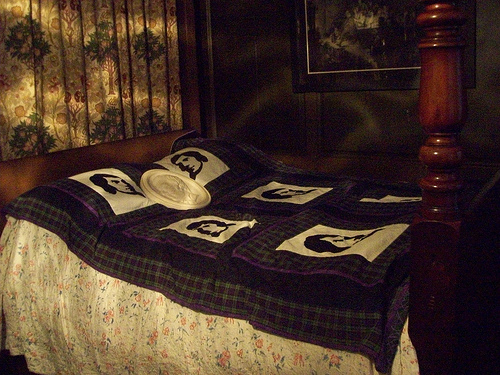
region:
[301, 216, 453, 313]
the pillow has picture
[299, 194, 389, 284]
the pillow has picture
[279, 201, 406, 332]
the pillow has picture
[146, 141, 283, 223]
the pillow has picture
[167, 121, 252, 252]
the pillow has picture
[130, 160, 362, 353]
this is a bed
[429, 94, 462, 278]
the bed is wooden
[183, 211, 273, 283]
this is a blanket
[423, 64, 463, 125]
the bed is brown in color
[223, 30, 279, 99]
this is the wall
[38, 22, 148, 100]
this is a curtain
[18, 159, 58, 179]
the bed is wooden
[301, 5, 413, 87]
this is a picture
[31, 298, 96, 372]
this is a bed cover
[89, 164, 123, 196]
this is a man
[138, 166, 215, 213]
The large white coin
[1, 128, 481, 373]
The dark blanket on the bed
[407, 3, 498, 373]
The post at the end of the bed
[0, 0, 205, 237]
The headboard of the bed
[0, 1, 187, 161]
The curtain behind the headboard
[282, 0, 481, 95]
The painting on the wall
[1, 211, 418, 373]
The light blanket on the bed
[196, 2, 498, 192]
The dark wall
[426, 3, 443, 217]
The reflection on the post at the foot of the bed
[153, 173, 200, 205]
The head on the large white coin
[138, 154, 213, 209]
a white disc on the bed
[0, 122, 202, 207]
the brown wooden headboard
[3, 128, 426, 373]
a purple and green bedspread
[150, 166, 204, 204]
head on the disc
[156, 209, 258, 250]
a white and black portrait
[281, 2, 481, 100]
a painting on the wall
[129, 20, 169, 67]
a green tree on the curtain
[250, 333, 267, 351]
a pink flower on the sheets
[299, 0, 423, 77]
a white line in the frame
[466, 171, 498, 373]
the foot board of the bed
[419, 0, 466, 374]
tall wooden bed post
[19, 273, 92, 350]
floral fabric hanging off the bed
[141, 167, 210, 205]
white fabric round pillow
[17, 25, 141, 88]
the pattern curtain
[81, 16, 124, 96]
tree print on the curtain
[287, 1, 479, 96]
pictured frame hanging on the wall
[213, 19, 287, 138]
dark wooden wall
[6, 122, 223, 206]
the wooden head board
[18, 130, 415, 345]
dark bedspread on bed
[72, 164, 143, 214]
a face printed on the dark blanket